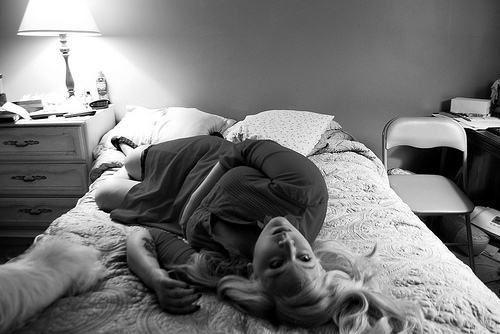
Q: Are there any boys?
A: No, there are no boys.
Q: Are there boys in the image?
A: No, there are no boys.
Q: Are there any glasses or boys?
A: No, there are no boys or glasses.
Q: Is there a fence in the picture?
A: No, there are no fences.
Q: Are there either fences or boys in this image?
A: No, there are no fences or boys.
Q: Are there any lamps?
A: Yes, there is a lamp.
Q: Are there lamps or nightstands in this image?
A: Yes, there is a lamp.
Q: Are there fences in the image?
A: No, there are no fences.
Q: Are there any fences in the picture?
A: No, there are no fences.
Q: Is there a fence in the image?
A: No, there are no fences.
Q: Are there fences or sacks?
A: No, there are no fences or sacks.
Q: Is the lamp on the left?
A: Yes, the lamp is on the left of the image.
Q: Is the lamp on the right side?
A: No, the lamp is on the left of the image.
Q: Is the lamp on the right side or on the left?
A: The lamp is on the left of the image.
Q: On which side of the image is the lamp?
A: The lamp is on the left of the image.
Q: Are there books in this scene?
A: No, there are no books.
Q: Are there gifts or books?
A: No, there are no books or gifts.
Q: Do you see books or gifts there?
A: No, there are no books or gifts.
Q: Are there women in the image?
A: Yes, there is a woman.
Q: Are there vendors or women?
A: Yes, there is a woman.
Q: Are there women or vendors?
A: Yes, there is a woman.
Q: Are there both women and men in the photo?
A: No, there is a woman but no men.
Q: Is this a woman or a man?
A: This is a woman.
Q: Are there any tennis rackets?
A: No, there are no tennis rackets.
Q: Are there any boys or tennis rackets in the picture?
A: No, there are no tennis rackets or boys.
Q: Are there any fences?
A: No, there are no fences.